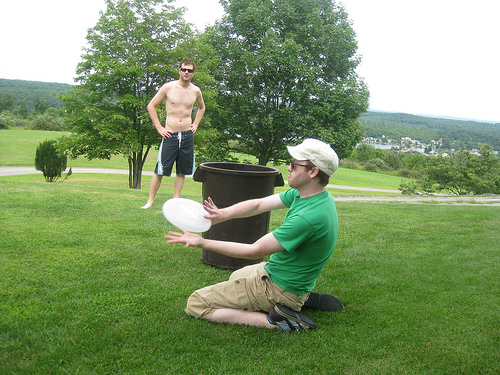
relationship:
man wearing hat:
[164, 138, 342, 330] [287, 138, 340, 176]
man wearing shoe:
[164, 138, 342, 330] [268, 305, 318, 333]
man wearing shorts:
[142, 59, 207, 214] [154, 131, 194, 176]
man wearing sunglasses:
[142, 59, 207, 214] [181, 68, 193, 73]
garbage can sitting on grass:
[193, 162, 284, 271] [0, 129, 498, 375]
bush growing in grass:
[34, 140, 73, 184] [0, 129, 498, 375]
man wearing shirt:
[164, 138, 342, 330] [265, 189, 339, 294]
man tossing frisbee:
[164, 138, 342, 330] [162, 198, 212, 233]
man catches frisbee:
[164, 138, 342, 330] [162, 198, 212, 233]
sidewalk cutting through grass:
[2, 166, 497, 203] [0, 129, 498, 375]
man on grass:
[164, 138, 342, 330] [0, 129, 498, 375]